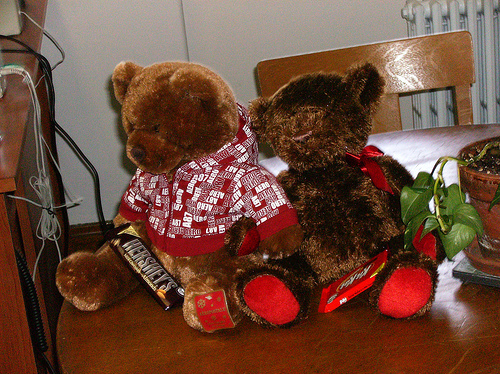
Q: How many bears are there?
A: Two.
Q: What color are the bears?
A: Brown.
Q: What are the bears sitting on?
A: A table.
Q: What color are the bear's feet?
A: Red.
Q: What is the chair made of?
A: Wood.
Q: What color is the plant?
A: Green.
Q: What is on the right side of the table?
A: A plant.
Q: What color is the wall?
A: It is white.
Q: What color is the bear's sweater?
A: Red and white.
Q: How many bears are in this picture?
A: Two.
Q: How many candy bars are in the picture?
A: Two.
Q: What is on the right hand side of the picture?
A: A plant.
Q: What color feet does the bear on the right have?
A: Red.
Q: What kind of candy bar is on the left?
A: Hersheys.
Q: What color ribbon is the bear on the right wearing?
A: Red.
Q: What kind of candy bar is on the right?
A: Kit Kat.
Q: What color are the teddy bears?
A: Brown.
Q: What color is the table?
A: Brown.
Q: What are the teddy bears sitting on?
A: A table.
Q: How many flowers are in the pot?
A: One.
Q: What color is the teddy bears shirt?
A: Red.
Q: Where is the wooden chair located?
A: Near table.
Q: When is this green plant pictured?
A: During day.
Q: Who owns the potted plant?
A: Owner.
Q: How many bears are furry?
A: Two.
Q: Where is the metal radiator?
A: Right corner.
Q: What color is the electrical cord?
A: White.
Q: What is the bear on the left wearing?
A: A red and white shirt.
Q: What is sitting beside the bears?
A: A plant.